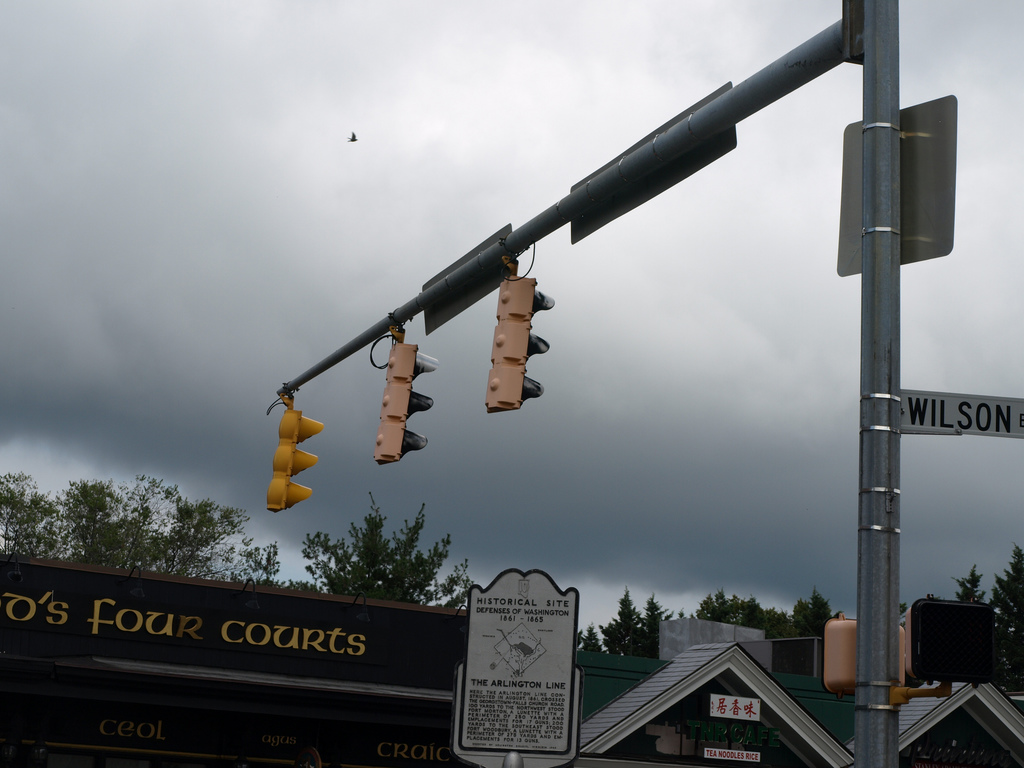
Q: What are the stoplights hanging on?
A: Pole.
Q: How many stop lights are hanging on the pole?
A: Three.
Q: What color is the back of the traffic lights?
A: Yellow.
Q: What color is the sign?
A: White.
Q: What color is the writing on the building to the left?
A: Yellow.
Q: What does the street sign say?
A: Wilson.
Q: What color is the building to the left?
A: Brown.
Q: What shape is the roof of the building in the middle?
A: Triangle.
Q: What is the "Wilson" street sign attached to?
A: A pole with an arm that juts out into the street.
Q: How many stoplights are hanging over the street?
A: Three.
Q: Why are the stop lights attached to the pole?
A: The pole is wired with electricity.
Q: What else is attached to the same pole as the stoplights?
A: Four street signs.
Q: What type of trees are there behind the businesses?
A: Deciduous trees.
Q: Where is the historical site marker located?
A: Across the street from the businesses.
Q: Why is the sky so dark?
A: Rain clouds are passing overhead.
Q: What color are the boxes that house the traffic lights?
A: Yellow.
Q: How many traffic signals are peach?
A: Two.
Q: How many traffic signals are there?
A: Three.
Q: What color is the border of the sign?
A: Black.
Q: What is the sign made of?
A: Metal.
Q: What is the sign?
A: Street sign.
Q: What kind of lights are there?
A: Traffic lights.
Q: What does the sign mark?
A: A landmark.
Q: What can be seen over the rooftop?
A: Trees.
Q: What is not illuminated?
A: The walk sign.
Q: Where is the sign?
A: At an intersection.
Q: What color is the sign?
A: Black and white.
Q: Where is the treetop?
A: Behind a building.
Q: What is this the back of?
A: Traffic sign.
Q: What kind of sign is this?
A: Walk/don't walk.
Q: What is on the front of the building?
A: Letters.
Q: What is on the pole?
A: Sign.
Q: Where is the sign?
A: On the pole.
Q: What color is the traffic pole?
A: Silver.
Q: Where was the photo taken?
A: Somewhere outdoors.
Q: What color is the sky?
A: Gray.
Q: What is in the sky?
A: Clouds.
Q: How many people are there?
A: None.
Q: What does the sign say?
A: Wilson.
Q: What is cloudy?
A: The sky.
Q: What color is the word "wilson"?
A: Black.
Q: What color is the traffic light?
A: Yellow.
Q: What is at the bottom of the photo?
A: A building.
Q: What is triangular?
A: Top of a building.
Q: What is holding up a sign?
A: Gray post.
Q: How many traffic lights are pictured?
A: Three.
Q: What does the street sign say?
A: "WILSON".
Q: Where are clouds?
A: In the sky.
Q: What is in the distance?
A: Trees.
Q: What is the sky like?
A: Cloudy.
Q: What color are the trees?
A: Green.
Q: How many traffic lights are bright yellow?
A: One.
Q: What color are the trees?
A: Green.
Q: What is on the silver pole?
A: An unreadable sign.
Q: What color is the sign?
A: White.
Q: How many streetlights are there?
A: Three.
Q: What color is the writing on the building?
A: Yellow.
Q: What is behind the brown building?
A: Trees.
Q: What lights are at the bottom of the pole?
A: Walk/don't walk lights.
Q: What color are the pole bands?
A: Silver.